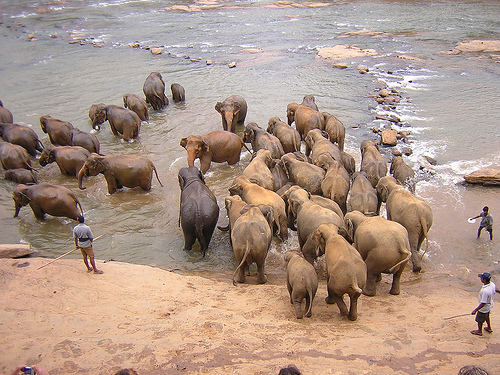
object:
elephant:
[70, 127, 100, 154]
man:
[470, 272, 495, 335]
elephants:
[0, 71, 433, 321]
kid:
[470, 206, 493, 241]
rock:
[463, 165, 500, 187]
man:
[73, 215, 104, 274]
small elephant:
[170, 83, 185, 103]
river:
[0, 0, 499, 295]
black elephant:
[178, 166, 220, 258]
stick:
[36, 232, 106, 270]